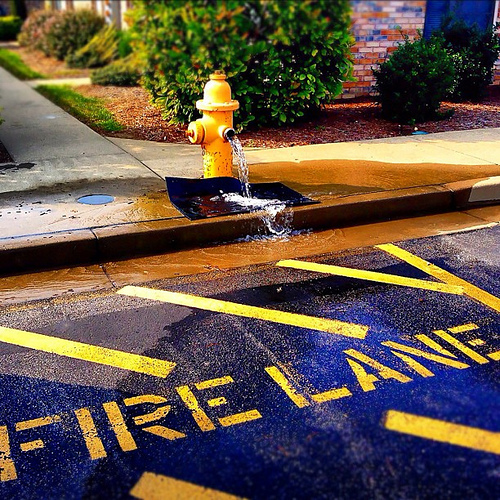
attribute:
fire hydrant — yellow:
[186, 68, 240, 181]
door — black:
[420, 2, 499, 67]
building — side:
[4, 0, 499, 149]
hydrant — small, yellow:
[172, 67, 253, 183]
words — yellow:
[0, 318, 499, 489]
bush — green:
[368, 25, 456, 123]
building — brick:
[23, 0, 498, 102]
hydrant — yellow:
[174, 60, 271, 195]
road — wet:
[4, 256, 482, 497]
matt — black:
[151, 160, 338, 212]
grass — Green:
[37, 70, 129, 138]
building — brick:
[1, 0, 498, 109]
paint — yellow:
[206, 147, 231, 174]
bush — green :
[368, 33, 462, 125]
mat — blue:
[161, 174, 321, 221]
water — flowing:
[201, 122, 272, 171]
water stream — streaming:
[227, 130, 266, 201]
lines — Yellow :
[0, 241, 499, 498]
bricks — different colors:
[358, 30, 382, 55]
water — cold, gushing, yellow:
[228, 138, 263, 210]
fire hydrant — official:
[190, 69, 243, 199]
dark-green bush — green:
[369, 25, 458, 122]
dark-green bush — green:
[428, 12, 498, 100]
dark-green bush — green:
[42, 8, 109, 67]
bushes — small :
[18, 7, 137, 87]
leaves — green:
[215, 13, 340, 92]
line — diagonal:
[106, 275, 370, 347]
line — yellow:
[139, 259, 341, 360]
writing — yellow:
[0, 322, 500, 482]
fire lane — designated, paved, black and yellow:
[7, 310, 479, 478]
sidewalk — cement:
[19, 159, 446, 217]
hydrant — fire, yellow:
[159, 74, 257, 194]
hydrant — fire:
[186, 72, 268, 211]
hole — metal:
[66, 190, 115, 210]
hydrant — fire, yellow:
[177, 73, 246, 183]